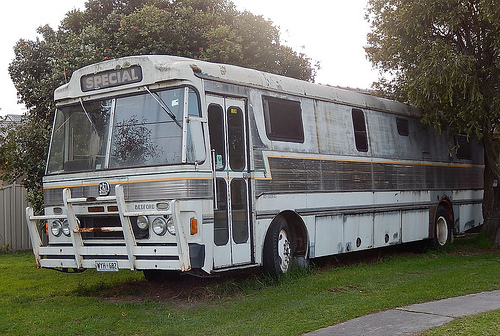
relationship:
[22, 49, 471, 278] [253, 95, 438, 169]
bus has windows